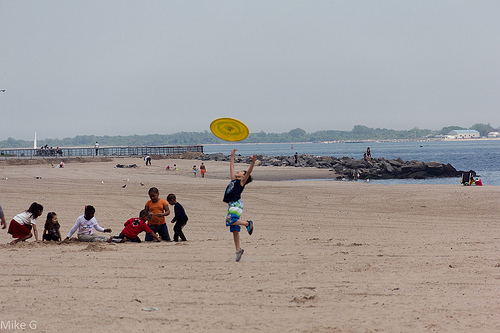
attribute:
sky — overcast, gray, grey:
[1, 2, 497, 164]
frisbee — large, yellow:
[210, 118, 251, 142]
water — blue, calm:
[3, 142, 498, 186]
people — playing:
[1, 184, 187, 243]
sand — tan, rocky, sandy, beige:
[1, 153, 499, 330]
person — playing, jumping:
[226, 148, 260, 260]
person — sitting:
[362, 145, 373, 166]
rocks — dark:
[331, 158, 482, 179]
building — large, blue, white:
[444, 128, 483, 140]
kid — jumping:
[225, 145, 257, 252]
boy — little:
[120, 218, 151, 236]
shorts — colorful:
[224, 201, 246, 226]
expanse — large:
[147, 155, 474, 177]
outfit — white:
[68, 205, 104, 240]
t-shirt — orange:
[144, 198, 168, 227]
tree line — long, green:
[1, 125, 496, 147]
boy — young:
[214, 147, 270, 270]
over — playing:
[164, 194, 188, 241]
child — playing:
[66, 205, 115, 243]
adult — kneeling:
[144, 156, 151, 164]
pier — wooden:
[1, 145, 203, 155]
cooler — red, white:
[474, 178, 483, 187]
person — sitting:
[461, 170, 477, 187]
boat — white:
[32, 133, 39, 151]